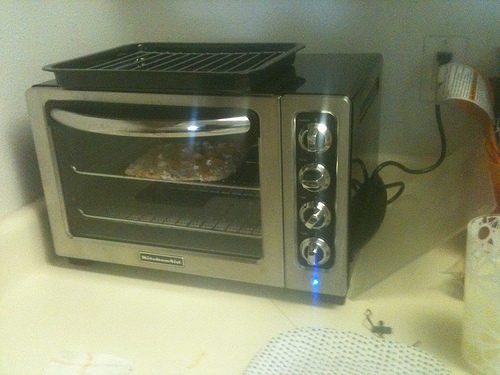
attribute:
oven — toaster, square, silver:
[28, 48, 390, 313]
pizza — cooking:
[120, 136, 250, 188]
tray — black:
[42, 33, 309, 94]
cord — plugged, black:
[371, 69, 451, 208]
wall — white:
[377, 41, 490, 160]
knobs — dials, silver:
[296, 111, 340, 279]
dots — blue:
[331, 350, 356, 360]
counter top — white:
[1, 157, 499, 375]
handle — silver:
[49, 104, 252, 146]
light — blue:
[309, 278, 326, 292]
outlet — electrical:
[418, 30, 471, 104]